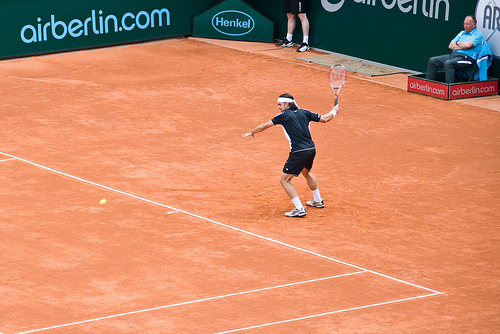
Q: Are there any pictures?
A: No, there are no pictures.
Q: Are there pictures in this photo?
A: No, there are no pictures.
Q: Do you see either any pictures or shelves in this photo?
A: No, there are no pictures or shelves.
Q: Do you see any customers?
A: No, there are no customers.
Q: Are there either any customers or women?
A: No, there are no customers or women.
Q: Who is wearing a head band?
A: The athlete is wearing a head band.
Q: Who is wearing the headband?
A: The athlete is wearing a head band.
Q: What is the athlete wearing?
A: The athlete is wearing a headband.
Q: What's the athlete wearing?
A: The athlete is wearing a headband.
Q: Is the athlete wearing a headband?
A: Yes, the athlete is wearing a headband.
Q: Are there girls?
A: No, there are no girls.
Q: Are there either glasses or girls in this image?
A: No, there are no girls or glasses.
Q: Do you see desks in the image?
A: No, there are no desks.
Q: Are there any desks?
A: No, there are no desks.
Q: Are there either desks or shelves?
A: No, there are no desks or shelves.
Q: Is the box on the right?
A: Yes, the box is on the right of the image.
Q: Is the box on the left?
A: No, the box is on the right of the image.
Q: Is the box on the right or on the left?
A: The box is on the right of the image.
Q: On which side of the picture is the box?
A: The box is on the right of the image.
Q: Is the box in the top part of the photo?
A: Yes, the box is in the top of the image.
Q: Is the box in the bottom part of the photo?
A: No, the box is in the top of the image.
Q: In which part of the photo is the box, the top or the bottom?
A: The box is in the top of the image.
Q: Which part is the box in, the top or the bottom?
A: The box is in the top of the image.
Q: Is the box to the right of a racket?
A: Yes, the box is to the right of a racket.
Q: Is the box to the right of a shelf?
A: No, the box is to the right of a racket.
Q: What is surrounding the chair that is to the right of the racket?
A: The box is surrounding the chair.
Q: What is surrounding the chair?
A: The box is surrounding the chair.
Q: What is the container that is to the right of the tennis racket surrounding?
A: The box is surrounding the chair.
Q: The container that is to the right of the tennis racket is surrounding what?
A: The box is surrounding the chair.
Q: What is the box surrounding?
A: The box is surrounding the chair.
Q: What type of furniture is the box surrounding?
A: The box is surrounding the chair.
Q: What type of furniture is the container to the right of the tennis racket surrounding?
A: The box is surrounding the chair.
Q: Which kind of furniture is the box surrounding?
A: The box is surrounding the chair.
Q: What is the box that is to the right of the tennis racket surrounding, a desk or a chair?
A: The box is surrounding a chair.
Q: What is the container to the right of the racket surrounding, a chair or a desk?
A: The box is surrounding a chair.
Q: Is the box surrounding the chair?
A: Yes, the box is surrounding the chair.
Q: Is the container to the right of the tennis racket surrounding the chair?
A: Yes, the box is surrounding the chair.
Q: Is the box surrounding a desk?
A: No, the box is surrounding the chair.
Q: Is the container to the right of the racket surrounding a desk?
A: No, the box is surrounding the chair.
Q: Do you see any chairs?
A: Yes, there is a chair.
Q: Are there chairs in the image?
A: Yes, there is a chair.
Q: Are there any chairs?
A: Yes, there is a chair.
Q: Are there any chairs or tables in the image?
A: Yes, there is a chair.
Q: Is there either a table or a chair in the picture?
A: Yes, there is a chair.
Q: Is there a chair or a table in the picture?
A: Yes, there is a chair.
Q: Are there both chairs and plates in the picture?
A: No, there is a chair but no plates.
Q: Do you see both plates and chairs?
A: No, there is a chair but no plates.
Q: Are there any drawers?
A: No, there are no drawers.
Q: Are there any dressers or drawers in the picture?
A: No, there are no drawers or dressers.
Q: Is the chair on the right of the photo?
A: Yes, the chair is on the right of the image.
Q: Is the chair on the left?
A: No, the chair is on the right of the image.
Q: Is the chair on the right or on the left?
A: The chair is on the right of the image.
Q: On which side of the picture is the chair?
A: The chair is on the right of the image.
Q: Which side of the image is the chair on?
A: The chair is on the right of the image.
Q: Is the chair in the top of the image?
A: Yes, the chair is in the top of the image.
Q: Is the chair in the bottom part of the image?
A: No, the chair is in the top of the image.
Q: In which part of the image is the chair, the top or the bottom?
A: The chair is in the top of the image.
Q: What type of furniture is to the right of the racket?
A: The piece of furniture is a chair.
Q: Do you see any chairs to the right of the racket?
A: Yes, there is a chair to the right of the racket.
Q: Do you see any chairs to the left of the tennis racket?
A: No, the chair is to the right of the tennis racket.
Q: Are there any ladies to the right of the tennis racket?
A: No, there is a chair to the right of the tennis racket.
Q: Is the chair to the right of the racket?
A: Yes, the chair is to the right of the racket.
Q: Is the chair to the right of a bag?
A: No, the chair is to the right of the racket.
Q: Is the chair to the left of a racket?
A: No, the chair is to the right of a racket.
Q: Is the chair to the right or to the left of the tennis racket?
A: The chair is to the right of the tennis racket.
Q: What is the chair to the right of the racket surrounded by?
A: The chair is surrounded by the box.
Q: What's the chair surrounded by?
A: The chair is surrounded by the box.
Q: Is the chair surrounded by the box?
A: Yes, the chair is surrounded by the box.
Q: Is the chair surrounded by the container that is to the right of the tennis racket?
A: Yes, the chair is surrounded by the box.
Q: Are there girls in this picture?
A: No, there are no girls.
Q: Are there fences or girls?
A: No, there are no girls or fences.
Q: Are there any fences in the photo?
A: No, there are no fences.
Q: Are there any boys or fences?
A: No, there are no fences or boys.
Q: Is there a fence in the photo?
A: No, there are no fences.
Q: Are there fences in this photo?
A: No, there are no fences.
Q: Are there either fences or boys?
A: No, there are no fences or boys.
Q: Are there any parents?
A: No, there are no parents.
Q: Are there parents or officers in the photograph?
A: No, there are no parents or officers.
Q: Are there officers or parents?
A: No, there are no parents or officers.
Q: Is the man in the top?
A: Yes, the man is in the top of the image.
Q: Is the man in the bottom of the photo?
A: No, the man is in the top of the image.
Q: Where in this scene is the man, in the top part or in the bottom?
A: The man is in the top of the image.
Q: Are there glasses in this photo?
A: No, there are no glasses.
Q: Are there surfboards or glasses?
A: No, there are no glasses or surfboards.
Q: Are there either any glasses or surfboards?
A: No, there are no glasses or surfboards.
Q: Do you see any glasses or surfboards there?
A: No, there are no glasses or surfboards.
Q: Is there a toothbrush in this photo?
A: No, there are no toothbrushes.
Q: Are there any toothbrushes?
A: No, there are no toothbrushes.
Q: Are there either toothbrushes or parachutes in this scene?
A: No, there are no toothbrushes or parachutes.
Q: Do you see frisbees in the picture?
A: No, there are no frisbees.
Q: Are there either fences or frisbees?
A: No, there are no frisbees or fences.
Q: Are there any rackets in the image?
A: Yes, there is a racket.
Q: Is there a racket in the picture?
A: Yes, there is a racket.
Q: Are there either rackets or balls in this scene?
A: Yes, there is a racket.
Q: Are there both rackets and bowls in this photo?
A: No, there is a racket but no bowls.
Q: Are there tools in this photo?
A: No, there are no tools.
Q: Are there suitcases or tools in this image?
A: No, there are no tools or suitcases.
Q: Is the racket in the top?
A: Yes, the racket is in the top of the image.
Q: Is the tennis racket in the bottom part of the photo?
A: No, the tennis racket is in the top of the image.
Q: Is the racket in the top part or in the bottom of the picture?
A: The racket is in the top of the image.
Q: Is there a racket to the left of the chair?
A: Yes, there is a racket to the left of the chair.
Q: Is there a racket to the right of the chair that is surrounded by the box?
A: No, the racket is to the left of the chair.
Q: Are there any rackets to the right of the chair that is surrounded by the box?
A: No, the racket is to the left of the chair.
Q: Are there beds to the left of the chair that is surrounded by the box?
A: No, there is a racket to the left of the chair.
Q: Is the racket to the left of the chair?
A: Yes, the racket is to the left of the chair.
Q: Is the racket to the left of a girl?
A: No, the racket is to the left of the chair.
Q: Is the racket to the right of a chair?
A: No, the racket is to the left of a chair.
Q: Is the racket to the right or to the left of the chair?
A: The racket is to the left of the chair.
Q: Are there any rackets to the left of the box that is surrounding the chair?
A: Yes, there is a racket to the left of the box.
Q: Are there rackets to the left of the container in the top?
A: Yes, there is a racket to the left of the box.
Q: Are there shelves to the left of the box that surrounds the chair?
A: No, there is a racket to the left of the box.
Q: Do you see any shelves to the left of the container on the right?
A: No, there is a racket to the left of the box.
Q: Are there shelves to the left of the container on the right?
A: No, there is a racket to the left of the box.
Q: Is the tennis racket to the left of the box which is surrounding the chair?
A: Yes, the tennis racket is to the left of the box.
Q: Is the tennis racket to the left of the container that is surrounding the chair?
A: Yes, the tennis racket is to the left of the box.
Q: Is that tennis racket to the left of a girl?
A: No, the tennis racket is to the left of the box.